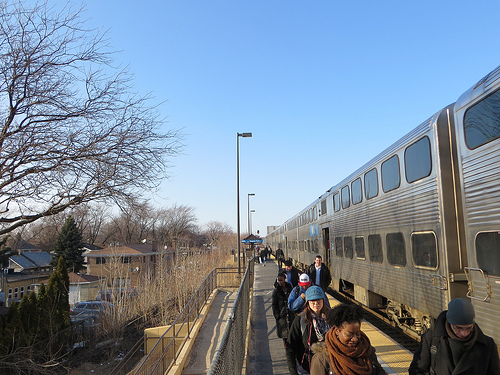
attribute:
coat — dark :
[406, 309, 497, 374]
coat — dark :
[283, 310, 337, 369]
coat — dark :
[268, 280, 298, 337]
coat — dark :
[303, 260, 333, 292]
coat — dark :
[280, 267, 302, 291]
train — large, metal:
[254, 62, 498, 359]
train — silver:
[243, 64, 495, 373]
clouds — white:
[3, 112, 282, 232]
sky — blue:
[7, 1, 489, 218]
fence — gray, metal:
[143, 243, 260, 367]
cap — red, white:
[295, 275, 312, 283]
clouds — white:
[174, 157, 224, 206]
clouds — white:
[0, 147, 335, 238]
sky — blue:
[125, 10, 345, 224]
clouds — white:
[199, 39, 329, 97]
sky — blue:
[5, 5, 499, 155]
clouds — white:
[162, 172, 301, 207]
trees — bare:
[119, 239, 187, 320]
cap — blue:
[304, 284, 324, 301]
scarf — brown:
[315, 330, 378, 370]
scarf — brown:
[320, 337, 377, 373]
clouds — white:
[32, 163, 266, 239]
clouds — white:
[50, 166, 307, 236]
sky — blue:
[5, 2, 477, 265]